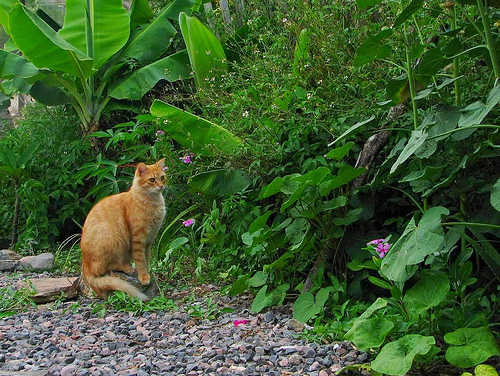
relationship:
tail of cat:
[80, 269, 150, 303] [79, 155, 168, 303]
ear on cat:
[135, 162, 147, 172] [79, 155, 168, 303]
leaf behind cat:
[149, 99, 245, 163] [79, 155, 168, 303]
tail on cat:
[80, 269, 150, 303] [79, 155, 168, 303]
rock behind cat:
[14, 275, 81, 306] [79, 155, 168, 303]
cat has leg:
[79, 155, 168, 303] [131, 230, 152, 288]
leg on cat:
[131, 230, 152, 288] [79, 155, 168, 303]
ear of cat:
[135, 162, 147, 172] [79, 155, 168, 303]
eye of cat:
[147, 175, 156, 183] [79, 155, 168, 303]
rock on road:
[14, 275, 81, 306] [2, 293, 380, 376]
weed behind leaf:
[82, 156, 132, 189] [149, 99, 245, 163]